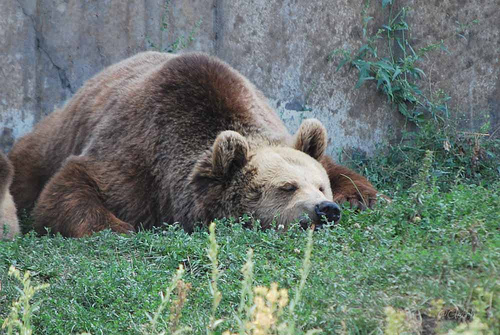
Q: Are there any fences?
A: No, there are no fences.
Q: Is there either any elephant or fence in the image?
A: No, there are no fences or elephants.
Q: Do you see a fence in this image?
A: No, there are no fences.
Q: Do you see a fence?
A: No, there are no fences.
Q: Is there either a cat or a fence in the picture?
A: No, there are no fences or cats.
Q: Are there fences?
A: No, there are no fences.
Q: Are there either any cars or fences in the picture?
A: No, there are no fences or cars.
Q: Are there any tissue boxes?
A: No, there are no tissue boxes.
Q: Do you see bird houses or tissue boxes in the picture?
A: No, there are no tissue boxes or bird houses.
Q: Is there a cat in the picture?
A: No, there are no cats.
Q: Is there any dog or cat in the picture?
A: No, there are no cats or dogs.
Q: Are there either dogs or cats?
A: No, there are no cats or dogs.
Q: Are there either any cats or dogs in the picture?
A: No, there are no cats or dogs.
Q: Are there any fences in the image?
A: No, there are no fences.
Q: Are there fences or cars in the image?
A: No, there are no fences or cars.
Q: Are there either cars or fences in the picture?
A: No, there are no fences or cars.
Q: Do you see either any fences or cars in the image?
A: No, there are no fences or cars.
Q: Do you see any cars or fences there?
A: No, there are no fences or cars.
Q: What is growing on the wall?
A: The weeds are growing on the wall.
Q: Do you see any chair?
A: No, there are no chairs.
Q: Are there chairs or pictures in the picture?
A: No, there are no chairs or pictures.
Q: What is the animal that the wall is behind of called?
A: The animal is a bear.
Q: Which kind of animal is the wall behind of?
A: The wall is behind the bear.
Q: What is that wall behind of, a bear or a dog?
A: The wall is behind a bear.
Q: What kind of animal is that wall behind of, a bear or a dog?
A: The wall is behind a bear.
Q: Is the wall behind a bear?
A: Yes, the wall is behind a bear.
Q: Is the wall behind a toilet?
A: No, the wall is behind a bear.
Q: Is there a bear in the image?
A: Yes, there is a bear.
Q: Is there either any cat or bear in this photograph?
A: Yes, there is a bear.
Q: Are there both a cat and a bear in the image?
A: No, there is a bear but no cats.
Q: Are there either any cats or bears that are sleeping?
A: Yes, the bear is sleeping.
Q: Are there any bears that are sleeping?
A: Yes, there is a bear that is sleeping.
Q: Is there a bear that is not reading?
A: Yes, there is a bear that is sleeping.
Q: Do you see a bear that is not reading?
A: Yes, there is a bear that is sleeping .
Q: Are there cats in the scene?
A: No, there are no cats.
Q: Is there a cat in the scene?
A: No, there are no cats.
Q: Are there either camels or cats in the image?
A: No, there are no cats or camels.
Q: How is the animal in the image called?
A: The animal is a bear.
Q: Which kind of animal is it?
A: The animal is a bear.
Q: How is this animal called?
A: This is a bear.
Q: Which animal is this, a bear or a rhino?
A: This is a bear.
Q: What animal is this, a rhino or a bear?
A: This is a bear.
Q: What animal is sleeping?
A: The animal is a bear.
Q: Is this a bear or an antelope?
A: This is a bear.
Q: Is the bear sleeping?
A: Yes, the bear is sleeping.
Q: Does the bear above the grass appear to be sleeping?
A: Yes, the bear is sleeping.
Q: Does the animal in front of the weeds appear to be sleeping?
A: Yes, the bear is sleeping.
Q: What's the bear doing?
A: The bear is sleeping.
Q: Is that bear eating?
A: No, the bear is sleeping.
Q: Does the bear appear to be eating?
A: No, the bear is sleeping.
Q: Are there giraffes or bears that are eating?
A: No, there is a bear but it is sleeping.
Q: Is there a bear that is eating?
A: No, there is a bear but it is sleeping.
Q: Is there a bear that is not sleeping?
A: No, there is a bear but it is sleeping.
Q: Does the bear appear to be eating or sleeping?
A: The bear is sleeping.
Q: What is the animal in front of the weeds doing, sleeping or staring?
A: The bear is sleeping.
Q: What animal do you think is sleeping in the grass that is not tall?
A: The bear is sleeping in the grass.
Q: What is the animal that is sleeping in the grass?
A: The animal is a bear.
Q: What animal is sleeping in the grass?
A: The animal is a bear.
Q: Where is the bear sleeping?
A: The bear is sleeping in the grass.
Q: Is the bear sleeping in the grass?
A: Yes, the bear is sleeping in the grass.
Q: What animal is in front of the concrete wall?
A: The bear is in front of the wall.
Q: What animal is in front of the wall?
A: The bear is in front of the wall.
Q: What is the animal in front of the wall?
A: The animal is a bear.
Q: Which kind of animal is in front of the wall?
A: The animal is a bear.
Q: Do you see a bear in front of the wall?
A: Yes, there is a bear in front of the wall.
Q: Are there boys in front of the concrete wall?
A: No, there is a bear in front of the wall.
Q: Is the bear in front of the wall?
A: Yes, the bear is in front of the wall.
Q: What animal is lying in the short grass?
A: The bear is lying in the grass.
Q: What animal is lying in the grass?
A: The bear is lying in the grass.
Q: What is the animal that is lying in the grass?
A: The animal is a bear.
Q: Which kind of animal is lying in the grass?
A: The animal is a bear.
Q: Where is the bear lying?
A: The bear is lying in the grass.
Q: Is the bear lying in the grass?
A: Yes, the bear is lying in the grass.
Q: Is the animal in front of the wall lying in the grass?
A: Yes, the bear is lying in the grass.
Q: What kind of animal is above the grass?
A: The animal is a bear.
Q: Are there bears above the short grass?
A: Yes, there is a bear above the grass.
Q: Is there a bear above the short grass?
A: Yes, there is a bear above the grass.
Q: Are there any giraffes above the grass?
A: No, there is a bear above the grass.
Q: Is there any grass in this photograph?
A: Yes, there is grass.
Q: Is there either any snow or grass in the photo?
A: Yes, there is grass.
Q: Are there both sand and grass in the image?
A: No, there is grass but no sand.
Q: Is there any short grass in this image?
A: Yes, there is short grass.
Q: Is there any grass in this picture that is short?
A: Yes, there is grass that is short.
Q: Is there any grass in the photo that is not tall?
A: Yes, there is short grass.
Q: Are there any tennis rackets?
A: No, there are no tennis rackets.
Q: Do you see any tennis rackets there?
A: No, there are no tennis rackets.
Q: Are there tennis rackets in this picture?
A: No, there are no tennis rackets.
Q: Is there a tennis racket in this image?
A: No, there are no rackets.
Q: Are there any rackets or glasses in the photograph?
A: No, there are no rackets or glasses.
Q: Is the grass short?
A: Yes, the grass is short.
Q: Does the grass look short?
A: Yes, the grass is short.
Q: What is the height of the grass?
A: The grass is short.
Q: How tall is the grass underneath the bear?
A: The grass is short.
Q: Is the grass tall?
A: No, the grass is short.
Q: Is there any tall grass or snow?
A: No, there is grass but it is short.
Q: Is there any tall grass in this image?
A: No, there is grass but it is short.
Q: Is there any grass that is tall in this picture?
A: No, there is grass but it is short.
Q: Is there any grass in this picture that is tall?
A: No, there is grass but it is short.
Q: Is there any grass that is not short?
A: No, there is grass but it is short.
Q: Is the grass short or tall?
A: The grass is short.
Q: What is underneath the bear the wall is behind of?
A: The grass is underneath the bear.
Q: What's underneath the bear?
A: The grass is underneath the bear.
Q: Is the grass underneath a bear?
A: Yes, the grass is underneath a bear.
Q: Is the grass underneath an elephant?
A: No, the grass is underneath a bear.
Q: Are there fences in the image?
A: No, there are no fences.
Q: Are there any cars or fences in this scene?
A: No, there are no fences or cars.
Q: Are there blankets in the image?
A: No, there are no blankets.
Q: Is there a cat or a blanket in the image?
A: No, there are no blankets or cats.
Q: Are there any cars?
A: No, there are no cars.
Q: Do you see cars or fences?
A: No, there are no cars or fences.